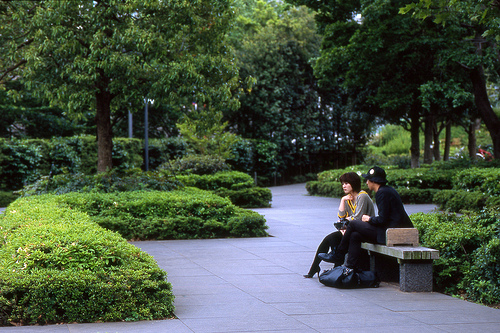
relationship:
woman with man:
[304, 172, 374, 278] [366, 166, 413, 244]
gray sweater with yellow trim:
[337, 190, 375, 219] [346, 191, 359, 211]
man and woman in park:
[300, 163, 420, 278] [6, 8, 498, 330]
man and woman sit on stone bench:
[300, 163, 420, 278] [358, 238, 439, 291]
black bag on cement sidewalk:
[307, 256, 373, 286] [123, 240, 498, 330]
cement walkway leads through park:
[188, 177, 390, 330] [6, 8, 498, 330]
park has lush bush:
[6, 8, 498, 330] [4, 136, 74, 183]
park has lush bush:
[6, 8, 498, 330] [4, 196, 174, 324]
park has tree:
[6, 8, 498, 330] [61, 5, 142, 179]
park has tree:
[6, 8, 498, 330] [343, 16, 436, 171]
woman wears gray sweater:
[304, 172, 374, 278] [338, 190, 375, 219]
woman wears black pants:
[304, 172, 374, 278] [308, 227, 342, 271]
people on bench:
[327, 174, 406, 243] [349, 230, 441, 295]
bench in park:
[349, 230, 441, 295] [6, 8, 498, 330]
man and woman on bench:
[300, 163, 420, 278] [360, 243, 440, 292]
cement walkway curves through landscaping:
[188, 177, 390, 330] [1, 5, 498, 318]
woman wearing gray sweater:
[304, 172, 374, 278] [337, 190, 375, 219]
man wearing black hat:
[366, 166, 413, 244] [359, 164, 390, 184]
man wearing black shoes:
[366, 159, 412, 278] [306, 262, 321, 280]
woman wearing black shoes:
[304, 172, 374, 278] [316, 248, 341, 265]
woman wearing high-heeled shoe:
[327, 160, 370, 269] [302, 265, 325, 281]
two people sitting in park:
[322, 169, 409, 297] [14, 13, 468, 304]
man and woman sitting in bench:
[300, 163, 420, 278] [335, 220, 441, 294]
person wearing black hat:
[359, 169, 413, 270] [359, 164, 390, 184]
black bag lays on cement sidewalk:
[307, 256, 373, 286] [123, 240, 498, 330]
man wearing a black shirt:
[366, 166, 413, 244] [373, 183, 411, 232]